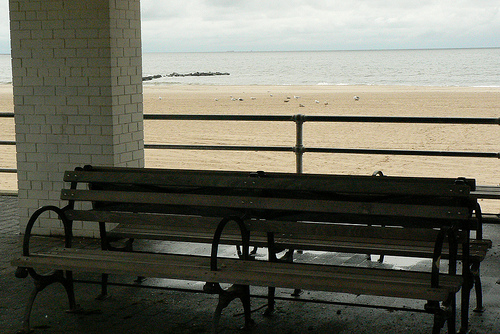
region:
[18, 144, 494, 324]
wooden bench with round arms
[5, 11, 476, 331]
wooden bench in beach view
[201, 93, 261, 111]
birds on sand in beach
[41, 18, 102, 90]
white brick patterned wall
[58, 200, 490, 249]
wooden slate on bench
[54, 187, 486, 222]
wooden slate on bench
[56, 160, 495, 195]
wooden slate on bench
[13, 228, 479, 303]
seat of wooden bench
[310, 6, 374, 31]
cloud in the sky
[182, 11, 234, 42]
cloud in the sky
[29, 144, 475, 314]
the bench is empty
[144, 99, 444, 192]
a black metal railings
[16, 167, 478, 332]
a long wooden bench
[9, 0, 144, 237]
a brick covered support pillar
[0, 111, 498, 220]
a metal railing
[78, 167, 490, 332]
a bench facing a railing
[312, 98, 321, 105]
a white bird on the beach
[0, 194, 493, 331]
a brick floor under benches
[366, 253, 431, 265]
water pooled on a brick floor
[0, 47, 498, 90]
the ocean water past the sand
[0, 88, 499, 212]
a sandy beach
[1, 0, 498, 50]
a pale blue and white cloudy sky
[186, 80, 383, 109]
Seagulls on the beach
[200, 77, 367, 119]
White seagulls on the beach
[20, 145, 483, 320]
The bench is made of wood and steel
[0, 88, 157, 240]
The building support is made of bricks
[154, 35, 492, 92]
The ocean is in the distance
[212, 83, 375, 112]
White seagulls on the sandy beach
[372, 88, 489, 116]
The beach is full of sand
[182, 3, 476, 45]
The sky is cloudy and overcast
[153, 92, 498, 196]
Metal bars act as railing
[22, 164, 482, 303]
The bench is wooden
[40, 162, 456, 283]
wooden bench on concrete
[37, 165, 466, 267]
long two part bench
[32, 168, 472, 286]
long two part wooden bench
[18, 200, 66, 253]
black metal bars on bench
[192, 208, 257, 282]
round black bar on bench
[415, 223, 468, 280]
round black bar on bench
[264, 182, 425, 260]
wooden slats on bench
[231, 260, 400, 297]
wooden bottom planks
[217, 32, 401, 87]
ocean in background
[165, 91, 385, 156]
large sand beach